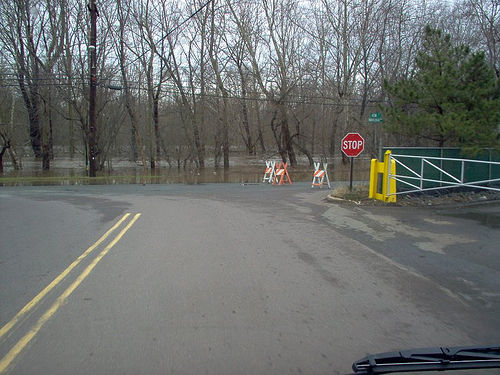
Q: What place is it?
A: It is a street.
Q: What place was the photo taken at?
A: It was taken at the street.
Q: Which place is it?
A: It is a street.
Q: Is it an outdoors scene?
A: Yes, it is outdoors.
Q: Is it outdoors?
A: Yes, it is outdoors.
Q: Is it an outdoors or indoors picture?
A: It is outdoors.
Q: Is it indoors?
A: No, it is outdoors.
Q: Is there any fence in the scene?
A: Yes, there is a fence.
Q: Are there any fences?
A: Yes, there is a fence.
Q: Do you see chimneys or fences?
A: Yes, there is a fence.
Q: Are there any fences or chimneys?
A: Yes, there is a fence.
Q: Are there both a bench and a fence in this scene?
A: No, there is a fence but no benches.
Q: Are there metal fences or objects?
A: Yes, there is a metal fence.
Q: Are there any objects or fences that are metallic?
A: Yes, the fence is metallic.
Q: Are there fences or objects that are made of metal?
A: Yes, the fence is made of metal.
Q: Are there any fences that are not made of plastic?
A: Yes, there is a fence that is made of metal.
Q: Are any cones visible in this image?
A: No, there are no cones.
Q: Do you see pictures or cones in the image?
A: No, there are no cones or pictures.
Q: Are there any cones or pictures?
A: No, there are no cones or pictures.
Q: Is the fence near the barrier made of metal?
A: Yes, the fence is made of metal.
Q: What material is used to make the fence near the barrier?
A: The fence is made of metal.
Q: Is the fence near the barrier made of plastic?
A: No, the fence is made of metal.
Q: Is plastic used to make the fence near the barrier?
A: No, the fence is made of metal.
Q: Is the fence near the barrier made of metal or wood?
A: The fence is made of metal.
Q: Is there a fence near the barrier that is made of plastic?
A: Yes, there is a fence near the barrier.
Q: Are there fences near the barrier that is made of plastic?
A: Yes, there is a fence near the barrier.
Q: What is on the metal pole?
A: The sign is on the pole.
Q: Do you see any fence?
A: Yes, there is a fence.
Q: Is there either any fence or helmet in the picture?
A: Yes, there is a fence.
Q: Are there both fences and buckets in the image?
A: No, there is a fence but no buckets.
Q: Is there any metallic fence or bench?
A: Yes, there is a metal fence.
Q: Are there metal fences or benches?
A: Yes, there is a metal fence.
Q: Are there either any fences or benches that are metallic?
A: Yes, the fence is metallic.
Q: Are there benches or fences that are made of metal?
A: Yes, the fence is made of metal.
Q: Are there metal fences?
A: Yes, there is a fence that is made of metal.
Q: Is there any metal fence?
A: Yes, there is a fence that is made of metal.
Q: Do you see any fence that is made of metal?
A: Yes, there is a fence that is made of metal.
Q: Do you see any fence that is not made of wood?
A: Yes, there is a fence that is made of metal.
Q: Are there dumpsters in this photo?
A: No, there are no dumpsters.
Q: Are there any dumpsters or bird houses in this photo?
A: No, there are no dumpsters or bird houses.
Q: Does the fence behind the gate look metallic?
A: Yes, the fence is metallic.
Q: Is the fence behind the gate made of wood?
A: No, the fence is made of metal.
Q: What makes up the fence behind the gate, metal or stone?
A: The fence is made of metal.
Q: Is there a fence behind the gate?
A: Yes, there is a fence behind the gate.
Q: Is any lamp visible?
A: No, there are no lamps.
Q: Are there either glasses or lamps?
A: No, there are no lamps or glasses.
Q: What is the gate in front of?
A: The gate is in front of the fence.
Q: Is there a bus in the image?
A: No, there are no buses.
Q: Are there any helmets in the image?
A: No, there are no helmets.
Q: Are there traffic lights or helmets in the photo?
A: No, there are no helmets or traffic lights.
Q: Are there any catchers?
A: No, there are no catchers.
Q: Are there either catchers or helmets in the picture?
A: No, there are no catchers or helmets.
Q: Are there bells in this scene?
A: No, there are no bells.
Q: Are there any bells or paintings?
A: No, there are no bells or paintings.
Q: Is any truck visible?
A: No, there are no trucks.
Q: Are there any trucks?
A: No, there are no trucks.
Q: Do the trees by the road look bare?
A: Yes, the trees are bare.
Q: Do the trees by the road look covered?
A: No, the trees are bare.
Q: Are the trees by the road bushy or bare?
A: The trees are bare.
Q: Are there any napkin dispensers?
A: No, there are no napkin dispensers.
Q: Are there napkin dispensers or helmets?
A: No, there are no napkin dispensers or helmets.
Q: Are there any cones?
A: No, there are no cones.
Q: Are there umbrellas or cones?
A: No, there are no cones or umbrellas.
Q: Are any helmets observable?
A: No, there are no helmets.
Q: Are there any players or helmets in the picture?
A: No, there are no helmets or players.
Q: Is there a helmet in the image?
A: No, there are no helmets.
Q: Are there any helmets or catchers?
A: No, there are no helmets or catchers.